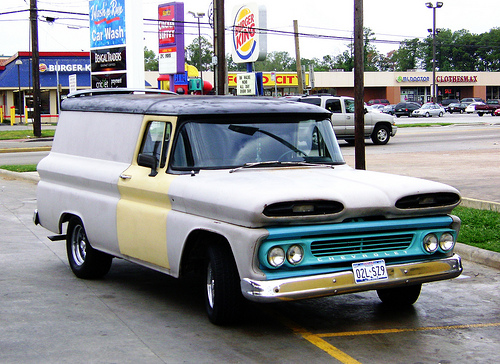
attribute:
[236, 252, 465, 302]
bumper — crooked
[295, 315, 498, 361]
yellow line — square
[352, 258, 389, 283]
plate — blue, white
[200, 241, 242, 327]
tire — black, rubber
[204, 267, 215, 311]
rim — metal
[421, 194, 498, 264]
leaves — green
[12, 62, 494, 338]
truck — colored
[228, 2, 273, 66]
sign — burger king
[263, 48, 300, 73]
leaves — green